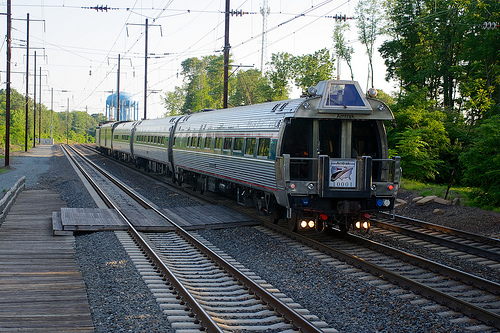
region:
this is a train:
[200, 79, 390, 207]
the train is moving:
[233, 73, 394, 217]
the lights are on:
[295, 216, 375, 231]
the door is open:
[285, 120, 379, 153]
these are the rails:
[375, 225, 470, 292]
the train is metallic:
[225, 106, 280, 128]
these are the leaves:
[403, 50, 496, 164]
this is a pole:
[216, 68, 236, 101]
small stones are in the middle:
[302, 266, 351, 318]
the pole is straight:
[138, 18, 156, 93]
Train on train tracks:
[81, 83, 393, 223]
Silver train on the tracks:
[177, 80, 409, 263]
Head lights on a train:
[293, 213, 374, 236]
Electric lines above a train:
[116, 21, 364, 76]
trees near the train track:
[364, 45, 488, 215]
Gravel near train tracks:
[69, 157, 181, 322]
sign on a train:
[319, 151, 367, 197]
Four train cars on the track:
[91, 115, 391, 192]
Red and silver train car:
[166, 105, 362, 212]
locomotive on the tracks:
[117, 103, 392, 204]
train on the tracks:
[83, 107, 410, 219]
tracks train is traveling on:
[389, 205, 491, 312]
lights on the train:
[293, 220, 378, 237]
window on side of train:
[175, 135, 273, 161]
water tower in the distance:
[102, 80, 144, 121]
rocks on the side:
[414, 191, 461, 211]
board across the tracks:
[34, 195, 256, 241]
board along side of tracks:
[4, 180, 94, 331]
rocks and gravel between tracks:
[278, 267, 345, 294]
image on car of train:
[328, 158, 361, 186]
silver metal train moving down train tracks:
[91, 71, 403, 241]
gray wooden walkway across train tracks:
[50, 185, 425, 237]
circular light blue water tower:
[100, 86, 137, 126]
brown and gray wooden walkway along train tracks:
[0, 171, 100, 328]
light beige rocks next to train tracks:
[391, 188, 465, 215]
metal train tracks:
[58, 139, 498, 331]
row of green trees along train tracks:
[1, 82, 120, 176]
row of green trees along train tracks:
[157, 0, 498, 219]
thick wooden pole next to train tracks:
[220, 1, 232, 210]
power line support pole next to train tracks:
[120, 13, 170, 176]